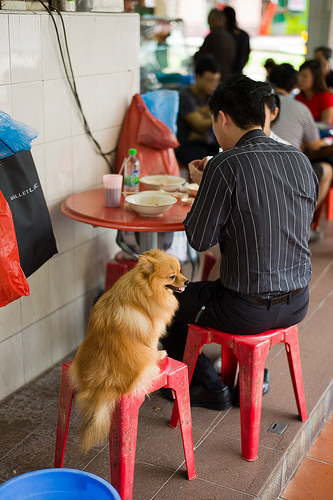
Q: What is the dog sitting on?
A: Plastic bench.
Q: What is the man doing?
A: Eating.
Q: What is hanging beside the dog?
A: Shopping bag.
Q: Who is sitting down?
A: Dog.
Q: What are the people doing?
A: Sitting down.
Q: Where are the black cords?
A: Wall.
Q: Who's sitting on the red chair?
A: Dog.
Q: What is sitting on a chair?
A: Small dog.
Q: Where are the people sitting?
A: Restaurant.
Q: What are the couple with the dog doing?
A: Eating.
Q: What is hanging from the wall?
A: Bags.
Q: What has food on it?
A: Round table.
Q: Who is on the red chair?
A: A dog.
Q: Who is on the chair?
A: A man in black pants and a shirt.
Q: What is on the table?
A: Plates and cups.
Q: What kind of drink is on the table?
A: A water bottle.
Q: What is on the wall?
A: Two black cords.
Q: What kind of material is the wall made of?
A: Tile.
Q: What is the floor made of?
A: Red tile.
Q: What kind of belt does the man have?
A: A black belt.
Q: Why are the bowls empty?
A: Because the man ate his food.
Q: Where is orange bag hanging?
A: On wall.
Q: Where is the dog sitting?
A: On red stool.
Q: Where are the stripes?
A: Man's shirt.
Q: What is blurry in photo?
A: People in background.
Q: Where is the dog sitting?
A: On the stool.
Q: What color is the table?
A: Red.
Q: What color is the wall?
A: White.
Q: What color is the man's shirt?
A: Black.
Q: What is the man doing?
A: Eating.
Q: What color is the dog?
A: Brown.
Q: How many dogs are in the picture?
A: One.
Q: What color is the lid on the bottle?
A: Green.